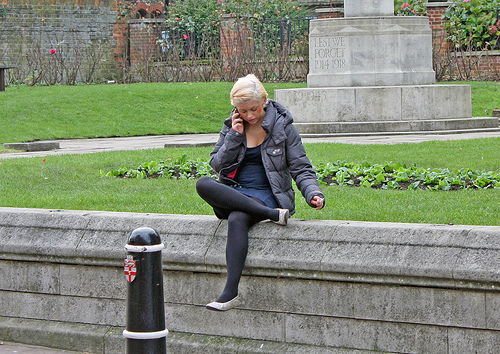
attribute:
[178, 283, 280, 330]
flats — white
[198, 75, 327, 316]
woman — black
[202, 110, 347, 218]
jacket — grey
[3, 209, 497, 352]
wall — short, concrete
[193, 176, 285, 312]
stockings — black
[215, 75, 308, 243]
woman — looking down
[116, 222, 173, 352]
pole — white, black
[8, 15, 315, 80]
shrubs — without leaves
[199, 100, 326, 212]
jacket — gray, heavy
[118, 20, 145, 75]
columns — brick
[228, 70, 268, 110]
hair — blonde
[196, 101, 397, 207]
woman's jacket — gray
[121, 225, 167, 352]
cigarette post — red, white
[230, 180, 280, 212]
skirt — blue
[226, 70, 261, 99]
hair — blonde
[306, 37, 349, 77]
letters — carved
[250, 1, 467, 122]
statue — concrete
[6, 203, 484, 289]
ledge — wall